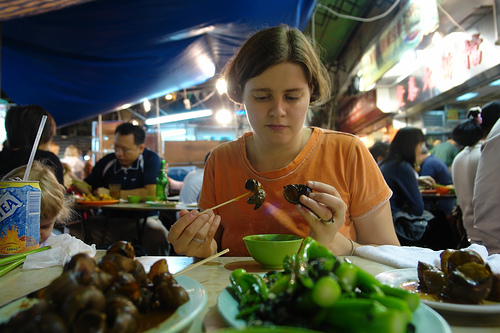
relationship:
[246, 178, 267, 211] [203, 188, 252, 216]
meat served on a stick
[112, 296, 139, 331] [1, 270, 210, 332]
escargot on top of dish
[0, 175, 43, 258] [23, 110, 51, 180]
can with a straw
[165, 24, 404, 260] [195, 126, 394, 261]
woman wearing shirt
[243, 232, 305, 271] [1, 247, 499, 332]
bowl on top of table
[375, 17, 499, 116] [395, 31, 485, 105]
sign written in asian language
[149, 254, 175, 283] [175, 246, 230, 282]
snail served on a stick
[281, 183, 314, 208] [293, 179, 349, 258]
shell held in left hand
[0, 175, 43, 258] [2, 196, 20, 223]
can of tea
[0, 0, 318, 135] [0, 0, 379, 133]
tarp covering ceiling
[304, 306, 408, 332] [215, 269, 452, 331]
vegetable on top of plate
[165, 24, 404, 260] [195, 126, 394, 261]
woman wearing orange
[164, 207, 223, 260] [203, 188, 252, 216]
hand holding stick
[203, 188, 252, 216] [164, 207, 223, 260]
stick held in hand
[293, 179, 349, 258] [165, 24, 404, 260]
left hand of woman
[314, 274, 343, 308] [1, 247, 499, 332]
vegetable on top of table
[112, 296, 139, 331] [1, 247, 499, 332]
escargot on top of table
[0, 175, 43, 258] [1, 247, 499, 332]
can on top of table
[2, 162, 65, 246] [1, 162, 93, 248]
head of a child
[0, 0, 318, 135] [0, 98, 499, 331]
tarp hanging over eating area